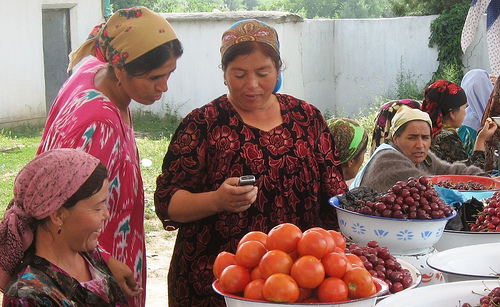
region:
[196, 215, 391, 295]
woman with head band on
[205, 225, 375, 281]
bowl of fresh tomatoes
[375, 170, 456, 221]
grapes in a bowl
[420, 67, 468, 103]
black and red head band on head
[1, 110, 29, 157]
grass against a fence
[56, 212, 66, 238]
red earring on lady's ear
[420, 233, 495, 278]
empty bowl on table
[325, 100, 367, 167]
green and brown head band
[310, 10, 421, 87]
white wooden fence in the yard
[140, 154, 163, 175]
white ball laying in yard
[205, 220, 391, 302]
A pile of tomatoes in a bowl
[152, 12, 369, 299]
A woman in a red floral dress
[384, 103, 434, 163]
A woman with a tan hair cover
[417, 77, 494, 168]
A woman with a black and red hair cover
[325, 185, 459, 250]
A white bowl with blue print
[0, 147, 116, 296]
A woman in a pink hair cover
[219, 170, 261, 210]
An electronic device in the woman's hand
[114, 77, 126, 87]
An earring in the woman's ear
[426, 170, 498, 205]
A bowl colored red on the inside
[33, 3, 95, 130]
A gray door in the background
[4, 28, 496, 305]
the scene is at a market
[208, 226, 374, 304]
the tomatoes are red in colour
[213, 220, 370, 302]
the tomatoes are ripe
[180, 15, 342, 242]
a woman is using a mobile phone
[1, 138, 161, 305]
a woman is laughing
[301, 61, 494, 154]
women seated down selling goods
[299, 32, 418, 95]
the wall is white in colour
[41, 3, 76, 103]
the door is open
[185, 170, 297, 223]
the mobile phone is black in colour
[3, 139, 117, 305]
the woman has black earings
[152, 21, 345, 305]
Woman looking at cell phone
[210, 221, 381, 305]
Tomatoes in a bowl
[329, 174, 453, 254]
Grapes in a bowl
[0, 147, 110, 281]
Smiling woman with pink bandana on her head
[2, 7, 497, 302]
Women standing and sitting behind table of fruits and vegetables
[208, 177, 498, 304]
Bowls of tomatoes and grapes on a table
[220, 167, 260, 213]
Cell phone in woman's right hand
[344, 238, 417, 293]
Bowl of grapes behind a bowl of tomatoes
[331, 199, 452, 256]
Blue designs on a white bowl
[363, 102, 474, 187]
Woman with yellow bandana and grey sweater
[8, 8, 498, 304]
women are gathered around a table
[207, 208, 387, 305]
a bowl of tomatoes on the table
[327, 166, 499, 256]
bowls of grapes on the table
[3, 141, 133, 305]
the woman on the far left is laughing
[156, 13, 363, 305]
the woman in the middle is looking at a cellphone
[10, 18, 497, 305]
the women all wear scarfs on their heads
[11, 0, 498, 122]
a stone wall is behind the women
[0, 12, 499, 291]
the women are talking to each other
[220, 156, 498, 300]
bowls of fruit and vegetables are on the table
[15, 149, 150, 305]
the woman on the far left is wearing a pink scarf